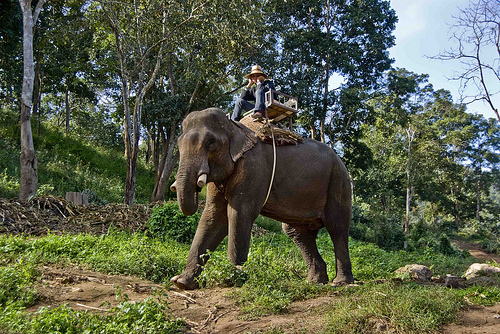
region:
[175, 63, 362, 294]
the man riding on an elephant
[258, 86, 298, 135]
the seat on the back of the elephant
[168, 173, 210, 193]
the cut tusks of the elephant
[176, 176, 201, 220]
the trunk of the elephant tuked under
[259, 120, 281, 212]
the rope under the elephant stomach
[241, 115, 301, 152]
the folded blacket on the back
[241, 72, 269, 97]
the hands on the mans face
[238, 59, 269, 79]
the hat on the head of the man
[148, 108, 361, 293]
the elepahnt walking in the grass and dirt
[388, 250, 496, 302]
the log on the ground behind the elephant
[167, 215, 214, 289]
leg of an elephant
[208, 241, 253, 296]
leg of an elephant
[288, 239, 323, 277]
leg of an elephant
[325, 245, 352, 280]
leg of an elephant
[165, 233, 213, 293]
a leg of an elephant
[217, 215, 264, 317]
a leg of an elephant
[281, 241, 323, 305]
a leg of an elephant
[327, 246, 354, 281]
a leg of an elephant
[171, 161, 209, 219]
nose of an elephant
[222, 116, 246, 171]
ear of an elephant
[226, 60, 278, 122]
man sitting atop elephant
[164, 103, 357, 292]
large dark brown elephant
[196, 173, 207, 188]
elephant has short white tusk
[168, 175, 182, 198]
elephant has short white tusk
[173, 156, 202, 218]
trunk of elephant is curled under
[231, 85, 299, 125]
man sitting in seat on elephant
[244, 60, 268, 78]
man wearing large white hat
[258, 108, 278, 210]
rope around elephant holding seat on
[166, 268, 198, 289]
large front foot of elephant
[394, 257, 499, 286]
rocks on ground behind elephant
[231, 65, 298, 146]
a person riding an elephant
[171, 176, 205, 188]
the elephant's tusks cut down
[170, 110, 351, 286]
a large gray elephant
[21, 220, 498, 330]
a rocky dirt and grass path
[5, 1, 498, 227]
trees on the hill behind the elephant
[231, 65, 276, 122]
rider with blue outfit and tan hat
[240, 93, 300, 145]
wooden seat and saddle on elephant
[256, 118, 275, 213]
rope to tie seat to elephant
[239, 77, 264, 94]
man's elbows on knees and hands on face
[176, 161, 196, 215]
the elephant's trunk curled under